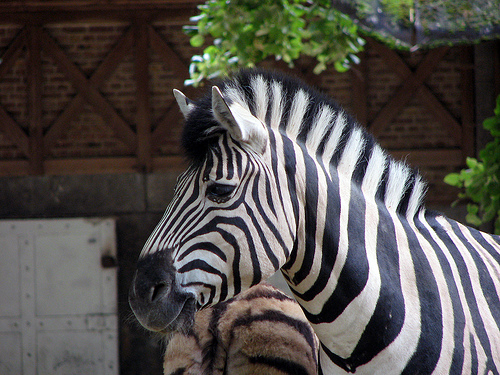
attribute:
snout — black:
[129, 269, 171, 307]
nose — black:
[122, 248, 175, 318]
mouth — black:
[137, 301, 194, 338]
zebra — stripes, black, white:
[109, 66, 499, 373]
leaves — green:
[212, 7, 358, 52]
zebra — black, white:
[127, 65, 470, 341]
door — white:
[6, 213, 124, 373]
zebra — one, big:
[201, 80, 437, 236]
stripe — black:
[291, 141, 318, 286]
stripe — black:
[293, 139, 343, 303]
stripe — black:
[396, 208, 441, 373]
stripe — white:
[313, 176, 382, 361]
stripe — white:
[410, 215, 457, 369]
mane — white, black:
[172, 74, 434, 221]